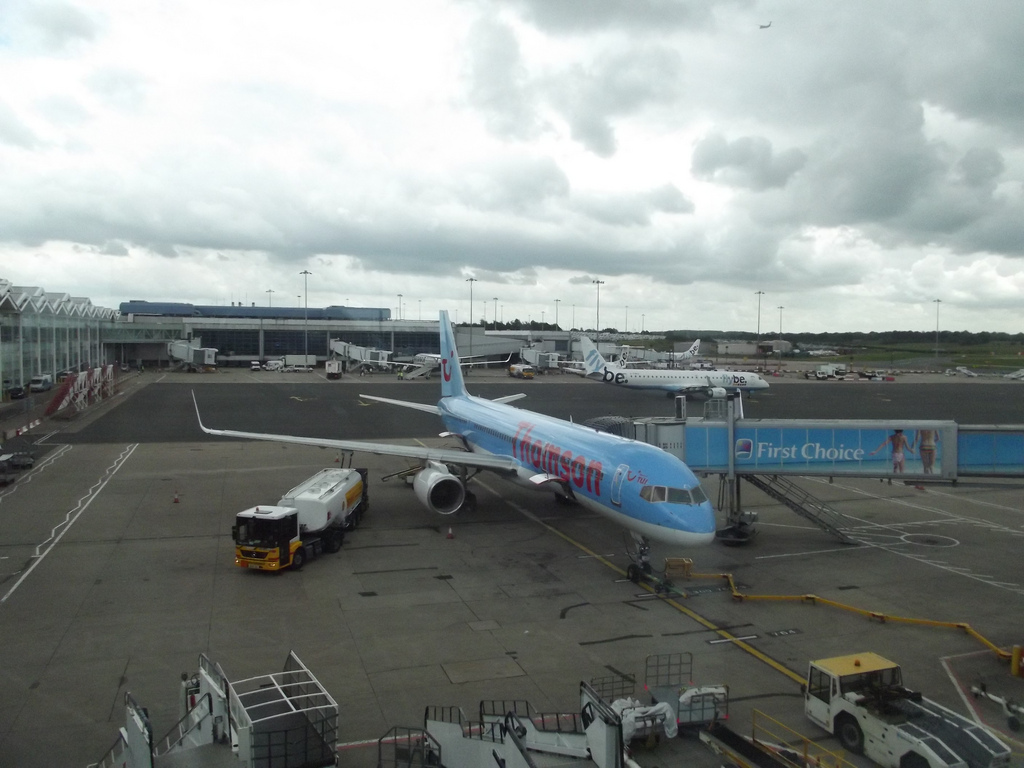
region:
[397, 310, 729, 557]
plane on the runaway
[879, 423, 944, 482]
photo of people on the plane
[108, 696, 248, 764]
stairs of the plane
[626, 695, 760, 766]
luggage carriers on the runway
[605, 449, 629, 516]
door on the plane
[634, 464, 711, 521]
windows on the plane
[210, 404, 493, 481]
wing of the plane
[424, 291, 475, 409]
tail of the plane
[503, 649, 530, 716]
The woman is holding a large orange.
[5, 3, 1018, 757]
An airport tarmac in the daytime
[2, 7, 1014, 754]
Outside of an airport with several airplanes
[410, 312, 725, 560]
A blue and red commercial airplane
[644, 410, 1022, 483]
A loading tunnel for the airplane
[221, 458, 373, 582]
Yellow and white luggage truck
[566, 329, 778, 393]
White commercial airplane entering the runway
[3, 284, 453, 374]
Side of the airport building with windows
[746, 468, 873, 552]
Portable metal staircase going into the plane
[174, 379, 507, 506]
Wing of an airplane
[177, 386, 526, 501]
Large wing of an airplane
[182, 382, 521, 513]
Large wing of a blue airplane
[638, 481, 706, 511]
Windows of a blue airplane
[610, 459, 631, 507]
Door of an airplane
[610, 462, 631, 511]
Door of a blue airplane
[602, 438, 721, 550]
Front of a airplane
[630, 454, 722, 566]
Front of a blue airplane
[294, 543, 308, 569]
Tire of a vehicle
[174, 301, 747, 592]
plane is parked at the gate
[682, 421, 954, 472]
advertisement on jetway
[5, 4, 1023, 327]
dark clouds in the sky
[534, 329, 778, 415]
plane driving toward runway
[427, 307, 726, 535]
plane body is painted blue with red writing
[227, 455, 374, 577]
yellow and white truck is driving away from plane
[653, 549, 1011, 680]
yellow hose is connected to plane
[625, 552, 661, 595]
plane's front wheels are on the yellow line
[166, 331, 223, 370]
this jetway is not being used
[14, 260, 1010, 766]
An airport.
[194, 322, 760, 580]
A light blue and grey plane with red lettering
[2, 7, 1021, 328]
Large white and grey clouds covering the sky.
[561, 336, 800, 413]
An airplane on the ground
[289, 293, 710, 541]
blue and white plane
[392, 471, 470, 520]
white engine on plane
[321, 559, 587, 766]
tarmac is dark grey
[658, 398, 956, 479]
blue and white billboard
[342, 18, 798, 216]
white and puffy clouds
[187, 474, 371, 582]
white truck near plane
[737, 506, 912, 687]
yellow lines on tarmac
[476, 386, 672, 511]
red logo on plane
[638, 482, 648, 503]
a window on a plane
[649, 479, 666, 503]
a window on a plane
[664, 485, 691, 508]
a window on a plane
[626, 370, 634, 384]
a window on a plane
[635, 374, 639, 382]
a window on a plane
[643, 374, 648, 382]
a window on a plane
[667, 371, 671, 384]
a window on a plane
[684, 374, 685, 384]
a window on a plane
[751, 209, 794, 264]
a white fluffy cloud